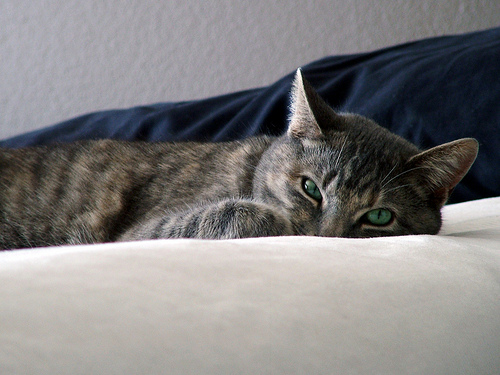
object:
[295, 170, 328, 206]
eye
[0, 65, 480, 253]
cat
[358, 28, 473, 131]
cover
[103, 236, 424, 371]
blanket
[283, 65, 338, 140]
ear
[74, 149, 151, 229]
astripes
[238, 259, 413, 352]
cover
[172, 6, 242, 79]
wall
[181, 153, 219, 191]
fur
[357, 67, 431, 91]
pillow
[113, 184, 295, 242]
leg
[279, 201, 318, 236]
whisker